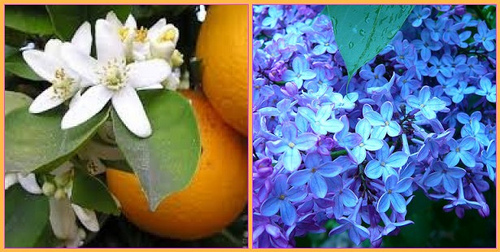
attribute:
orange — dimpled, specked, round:
[107, 87, 248, 240]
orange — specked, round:
[194, 5, 246, 133]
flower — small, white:
[49, 21, 169, 139]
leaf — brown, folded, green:
[110, 88, 202, 211]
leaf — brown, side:
[5, 103, 113, 172]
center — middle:
[99, 62, 131, 92]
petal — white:
[94, 18, 129, 69]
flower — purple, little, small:
[365, 101, 401, 143]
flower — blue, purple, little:
[397, 68, 421, 98]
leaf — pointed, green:
[327, 7, 417, 97]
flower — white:
[22, 21, 96, 113]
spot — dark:
[373, 53, 402, 79]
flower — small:
[443, 79, 476, 104]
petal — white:
[113, 85, 152, 139]